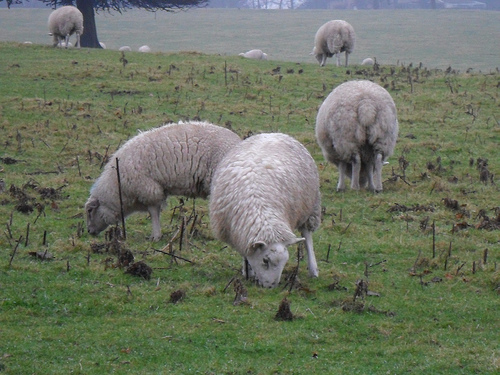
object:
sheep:
[47, 6, 84, 49]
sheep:
[208, 133, 323, 289]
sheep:
[65, 120, 241, 244]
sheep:
[315, 79, 399, 192]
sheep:
[310, 19, 357, 68]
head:
[246, 243, 289, 290]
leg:
[147, 203, 164, 242]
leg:
[301, 227, 320, 277]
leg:
[350, 155, 362, 189]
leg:
[336, 162, 347, 193]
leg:
[373, 153, 384, 192]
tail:
[357, 98, 377, 126]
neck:
[230, 205, 297, 256]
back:
[314, 80, 399, 193]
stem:
[115, 157, 126, 239]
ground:
[0, 7, 499, 375]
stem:
[179, 217, 184, 250]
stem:
[42, 230, 47, 245]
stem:
[24, 223, 29, 247]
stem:
[431, 219, 436, 258]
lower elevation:
[0, 9, 499, 73]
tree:
[0, 0, 210, 49]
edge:
[0, 38, 499, 76]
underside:
[336, 146, 383, 191]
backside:
[327, 20, 355, 67]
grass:
[0, 8, 500, 375]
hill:
[0, 0, 499, 10]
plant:
[275, 298, 294, 321]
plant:
[15, 203, 35, 215]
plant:
[124, 260, 153, 280]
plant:
[440, 197, 458, 209]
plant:
[353, 279, 369, 302]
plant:
[476, 157, 490, 186]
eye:
[262, 258, 268, 264]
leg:
[336, 50, 340, 67]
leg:
[344, 51, 349, 67]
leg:
[76, 32, 81, 49]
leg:
[65, 35, 70, 49]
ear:
[250, 241, 267, 252]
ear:
[285, 238, 306, 246]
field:
[0, 9, 500, 375]